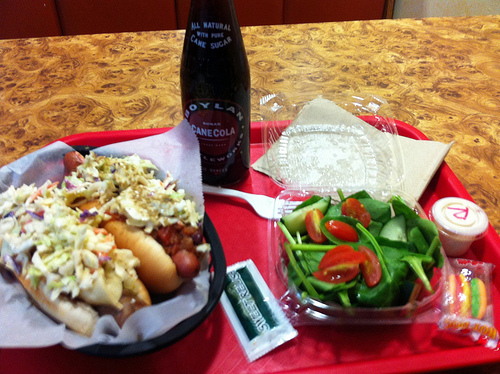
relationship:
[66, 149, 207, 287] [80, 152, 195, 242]
hotdog with toppings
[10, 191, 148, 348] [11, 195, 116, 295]
hotdog with toppings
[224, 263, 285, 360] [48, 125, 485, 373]
relish on tray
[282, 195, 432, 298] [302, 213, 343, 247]
salad with tomato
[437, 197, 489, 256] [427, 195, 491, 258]
container of dressing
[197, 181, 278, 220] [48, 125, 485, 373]
fork on tray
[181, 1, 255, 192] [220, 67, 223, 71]
bottle of soda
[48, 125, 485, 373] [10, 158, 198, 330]
tray of food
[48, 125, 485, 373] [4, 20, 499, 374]
tray on table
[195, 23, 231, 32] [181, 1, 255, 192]
text on bottle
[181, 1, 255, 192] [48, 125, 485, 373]
bottle on tray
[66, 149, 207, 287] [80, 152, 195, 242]
hotdog with slaw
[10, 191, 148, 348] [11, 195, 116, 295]
hotdog with slaw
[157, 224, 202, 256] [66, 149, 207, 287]
chili on hotdog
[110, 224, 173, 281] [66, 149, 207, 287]
bun of hotdog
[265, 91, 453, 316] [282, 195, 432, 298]
container with salad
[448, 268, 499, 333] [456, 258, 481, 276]
candy with bag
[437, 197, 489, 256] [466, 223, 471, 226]
container of dressing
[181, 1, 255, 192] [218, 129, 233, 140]
bottle of cola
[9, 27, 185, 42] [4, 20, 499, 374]
edge of table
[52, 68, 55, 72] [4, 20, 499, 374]
part of table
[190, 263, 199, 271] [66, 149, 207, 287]
portion of hotdog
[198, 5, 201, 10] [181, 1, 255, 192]
part of bottle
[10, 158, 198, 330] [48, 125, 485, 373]
food on tray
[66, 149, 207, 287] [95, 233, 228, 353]
hotdog in basket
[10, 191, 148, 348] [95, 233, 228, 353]
hotdog in basket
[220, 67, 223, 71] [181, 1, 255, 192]
soda in bottle